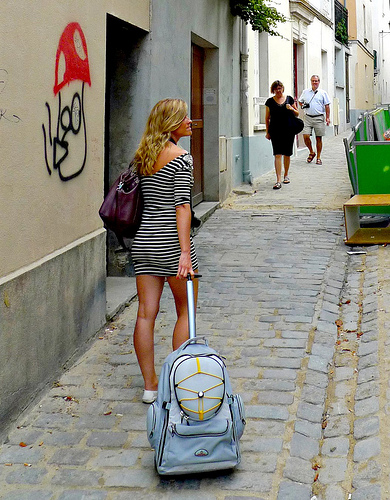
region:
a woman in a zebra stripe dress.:
[129, 99, 198, 404]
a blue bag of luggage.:
[142, 273, 245, 484]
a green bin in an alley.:
[340, 101, 389, 250]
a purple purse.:
[96, 148, 151, 253]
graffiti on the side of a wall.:
[34, 10, 91, 182]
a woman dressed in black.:
[250, 73, 305, 195]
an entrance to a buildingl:
[187, 27, 221, 229]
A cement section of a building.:
[0, 228, 108, 449]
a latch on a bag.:
[196, 389, 207, 404]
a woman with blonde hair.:
[132, 92, 195, 179]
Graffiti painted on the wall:
[32, 16, 96, 184]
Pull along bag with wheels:
[127, 266, 254, 479]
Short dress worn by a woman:
[124, 137, 205, 277]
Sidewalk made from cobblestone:
[223, 235, 315, 343]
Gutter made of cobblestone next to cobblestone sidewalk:
[299, 243, 380, 430]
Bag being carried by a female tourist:
[95, 158, 161, 247]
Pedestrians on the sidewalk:
[262, 73, 327, 191]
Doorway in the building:
[181, 22, 227, 224]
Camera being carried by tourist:
[294, 95, 317, 112]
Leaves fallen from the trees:
[334, 296, 373, 343]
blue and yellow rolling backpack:
[152, 339, 246, 479]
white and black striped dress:
[127, 150, 196, 276]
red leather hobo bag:
[97, 166, 146, 233]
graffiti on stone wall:
[50, 23, 95, 184]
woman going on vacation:
[108, 98, 242, 475]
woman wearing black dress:
[265, 80, 301, 189]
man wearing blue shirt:
[298, 74, 329, 160]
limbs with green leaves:
[232, 2, 294, 43]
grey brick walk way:
[0, 143, 344, 499]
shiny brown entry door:
[189, 43, 211, 207]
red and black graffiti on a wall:
[31, 15, 98, 183]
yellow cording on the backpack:
[184, 359, 214, 418]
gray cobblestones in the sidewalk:
[268, 282, 332, 413]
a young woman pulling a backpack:
[118, 82, 242, 487]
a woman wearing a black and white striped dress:
[95, 92, 223, 359]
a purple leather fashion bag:
[97, 159, 158, 244]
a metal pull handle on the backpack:
[178, 273, 207, 336]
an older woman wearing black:
[265, 69, 297, 192]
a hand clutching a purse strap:
[286, 102, 301, 114]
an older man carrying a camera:
[303, 76, 328, 162]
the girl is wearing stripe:
[113, 149, 258, 323]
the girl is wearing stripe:
[104, 85, 270, 468]